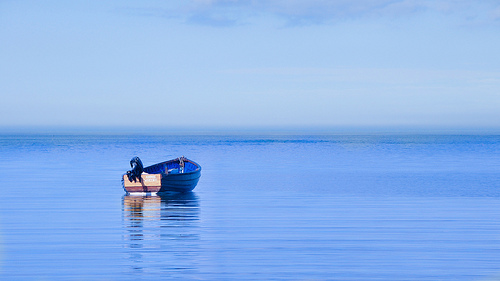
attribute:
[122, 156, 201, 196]
boat — empty, motorboat, blue, brown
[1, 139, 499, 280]
water — calm, blue, dark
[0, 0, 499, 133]
sky — blue, hazy, cloudy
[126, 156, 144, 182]
engine — motor, black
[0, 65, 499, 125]
cloud — white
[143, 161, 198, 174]
interior — blue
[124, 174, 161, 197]
stern — brown